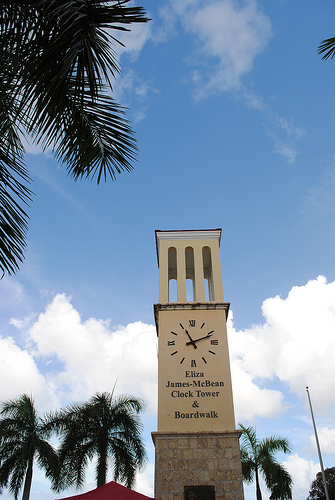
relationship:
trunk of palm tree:
[20, 453, 35, 498] [0, 394, 73, 497]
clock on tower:
[165, 318, 219, 367] [149, 225, 244, 494]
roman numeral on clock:
[209, 339, 219, 343] [165, 318, 219, 367]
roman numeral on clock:
[205, 346, 217, 357] [165, 318, 219, 367]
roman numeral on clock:
[201, 354, 207, 366] [168, 317, 217, 366]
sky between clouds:
[0, 2, 333, 497] [0, 273, 333, 498]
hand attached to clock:
[193, 334, 216, 346] [160, 315, 220, 375]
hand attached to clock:
[181, 325, 200, 349] [165, 318, 219, 367]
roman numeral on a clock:
[188, 358, 199, 368] [167, 319, 221, 371]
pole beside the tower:
[303, 384, 324, 488] [149, 225, 244, 494]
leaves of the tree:
[51, 387, 144, 489] [51, 391, 144, 489]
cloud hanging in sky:
[24, 291, 158, 414] [0, 2, 333, 497]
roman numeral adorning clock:
[187, 318, 196, 326] [165, 318, 219, 367]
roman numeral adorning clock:
[209, 338, 218, 345] [165, 318, 219, 367]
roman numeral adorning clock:
[191, 359, 197, 367] [165, 318, 219, 367]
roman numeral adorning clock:
[166, 339, 176, 346] [165, 318, 219, 367]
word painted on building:
[173, 409, 219, 418] [150, 227, 245, 498]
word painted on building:
[170, 389, 193, 397] [150, 227, 245, 498]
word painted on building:
[194, 388, 220, 397] [150, 227, 245, 498]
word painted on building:
[164, 379, 224, 386] [150, 227, 245, 498]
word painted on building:
[184, 369, 204, 376] [150, 227, 245, 498]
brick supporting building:
[157, 437, 167, 448] [150, 227, 245, 498]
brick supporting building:
[176, 437, 188, 444] [150, 227, 245, 498]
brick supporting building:
[212, 467, 228, 479] [150, 227, 245, 498]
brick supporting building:
[223, 445, 233, 459] [150, 227, 245, 498]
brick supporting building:
[154, 480, 174, 492] [150, 227, 245, 498]